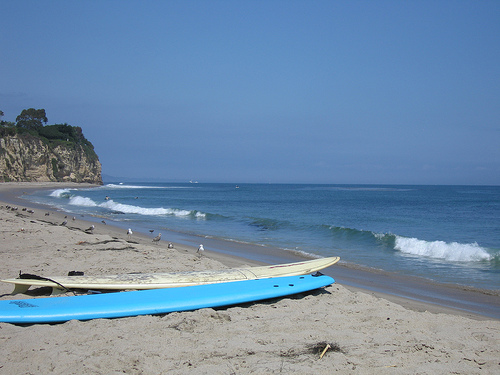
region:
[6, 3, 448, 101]
The sky is blue.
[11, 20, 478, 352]
The sport is surfing.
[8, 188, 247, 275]
The seagulls are at the beach.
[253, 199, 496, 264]
The waves are breaking.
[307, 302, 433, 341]
This is a sandy beach.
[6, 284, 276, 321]
The surfboard is blue.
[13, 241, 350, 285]
The surfboard is white.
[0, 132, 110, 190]
That is a big cliff.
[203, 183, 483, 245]
The ocean is blue.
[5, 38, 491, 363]
The weather is clear and sunny.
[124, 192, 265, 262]
small wave of water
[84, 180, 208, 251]
small wave of water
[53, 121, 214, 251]
small wave of water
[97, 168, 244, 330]
small wave of water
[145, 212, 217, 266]
small wave of water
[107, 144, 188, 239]
small wave of water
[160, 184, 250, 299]
small wave of water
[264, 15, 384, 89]
blue of daytime sky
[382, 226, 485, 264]
white water of crashing wave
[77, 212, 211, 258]
seagulls standing on beach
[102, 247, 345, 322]
two surfers on sand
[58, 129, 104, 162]
green vegetation on cliff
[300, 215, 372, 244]
wave on water surface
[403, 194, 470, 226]
calm blue ocean water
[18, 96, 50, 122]
tree tops on cliff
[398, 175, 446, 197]
sky meeting ocean on horizon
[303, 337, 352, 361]
dried vegetation on beach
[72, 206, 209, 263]
the birds are on the shore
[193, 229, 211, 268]
the bird is white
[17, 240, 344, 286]
the board is white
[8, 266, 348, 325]
the board is blue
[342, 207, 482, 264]
the wave is crashing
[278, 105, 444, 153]
the horizon is blue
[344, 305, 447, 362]
the sand is brown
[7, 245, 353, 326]
the boards are side by side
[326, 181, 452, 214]
the water is blue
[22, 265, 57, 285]
the board has a leash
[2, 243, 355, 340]
surfboards on beach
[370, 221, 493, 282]
wave cresting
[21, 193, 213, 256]
seagulls on beach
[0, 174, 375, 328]
surfboards and seagulls on beach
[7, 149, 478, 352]
sandy shoreline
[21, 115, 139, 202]
cliff overlooking ocean or sea water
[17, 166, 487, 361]
sandy beach with birds and surfboards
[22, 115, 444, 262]
land in far distance over water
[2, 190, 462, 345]
surfboards near water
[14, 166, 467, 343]
surfboards on ocean beach